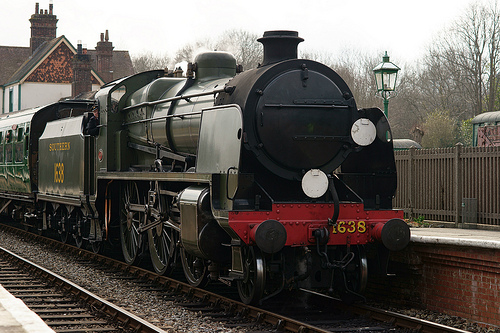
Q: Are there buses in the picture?
A: No, there are no buses.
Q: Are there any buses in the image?
A: No, there are no buses.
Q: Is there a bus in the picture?
A: No, there are no buses.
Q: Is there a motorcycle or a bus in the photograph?
A: No, there are no buses or motorcycles.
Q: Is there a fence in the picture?
A: Yes, there is a fence.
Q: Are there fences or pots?
A: Yes, there is a fence.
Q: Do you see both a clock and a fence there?
A: No, there is a fence but no clocks.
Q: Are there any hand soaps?
A: No, there are no hand soaps.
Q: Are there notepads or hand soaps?
A: No, there are no hand soaps or notepads.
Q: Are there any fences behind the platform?
A: Yes, there is a fence behind the platform.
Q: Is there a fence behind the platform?
A: Yes, there is a fence behind the platform.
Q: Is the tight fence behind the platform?
A: Yes, the fence is behind the platform.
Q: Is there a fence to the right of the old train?
A: Yes, there is a fence to the right of the train.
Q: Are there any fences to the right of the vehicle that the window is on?
A: Yes, there is a fence to the right of the train.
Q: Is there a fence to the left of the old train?
A: No, the fence is to the right of the train.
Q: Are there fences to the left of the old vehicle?
A: No, the fence is to the right of the train.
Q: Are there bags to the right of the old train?
A: No, there is a fence to the right of the train.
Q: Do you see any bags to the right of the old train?
A: No, there is a fence to the right of the train.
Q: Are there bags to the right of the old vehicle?
A: No, there is a fence to the right of the train.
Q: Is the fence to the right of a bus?
A: No, the fence is to the right of the train.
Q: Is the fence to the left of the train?
A: No, the fence is to the right of the train.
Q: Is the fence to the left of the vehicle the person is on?
A: No, the fence is to the right of the train.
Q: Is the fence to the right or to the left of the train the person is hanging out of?
A: The fence is to the right of the train.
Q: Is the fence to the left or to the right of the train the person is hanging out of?
A: The fence is to the right of the train.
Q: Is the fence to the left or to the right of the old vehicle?
A: The fence is to the right of the train.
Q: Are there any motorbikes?
A: No, there are no motorbikes.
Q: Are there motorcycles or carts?
A: No, there are no motorcycles or carts.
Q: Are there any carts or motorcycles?
A: No, there are no motorcycles or carts.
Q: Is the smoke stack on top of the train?
A: Yes, the smoke stack is on top of the train.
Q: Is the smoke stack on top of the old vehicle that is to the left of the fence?
A: Yes, the smoke stack is on top of the train.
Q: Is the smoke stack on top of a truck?
A: No, the smoke stack is on top of the train.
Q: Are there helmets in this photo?
A: No, there are no helmets.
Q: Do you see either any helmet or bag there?
A: No, there are no helmets or bags.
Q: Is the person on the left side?
A: Yes, the person is on the left of the image.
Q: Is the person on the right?
A: No, the person is on the left of the image.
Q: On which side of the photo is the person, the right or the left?
A: The person is on the left of the image.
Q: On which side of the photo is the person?
A: The person is on the left of the image.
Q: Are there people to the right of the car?
A: Yes, there is a person to the right of the car.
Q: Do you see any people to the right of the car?
A: Yes, there is a person to the right of the car.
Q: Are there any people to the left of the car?
A: No, the person is to the right of the car.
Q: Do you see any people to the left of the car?
A: No, the person is to the right of the car.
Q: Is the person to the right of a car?
A: Yes, the person is to the right of a car.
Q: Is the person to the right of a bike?
A: No, the person is to the right of a car.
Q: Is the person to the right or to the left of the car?
A: The person is to the right of the car.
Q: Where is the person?
A: The person is on the train.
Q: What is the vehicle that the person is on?
A: The vehicle is a train.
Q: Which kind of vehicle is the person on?
A: The person is on the train.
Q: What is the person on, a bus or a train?
A: The person is on a train.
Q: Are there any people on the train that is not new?
A: Yes, there is a person on the train.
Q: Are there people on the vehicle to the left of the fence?
A: Yes, there is a person on the train.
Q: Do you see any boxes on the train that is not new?
A: No, there is a person on the train.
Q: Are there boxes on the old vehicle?
A: No, there is a person on the train.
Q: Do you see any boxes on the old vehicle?
A: No, there is a person on the train.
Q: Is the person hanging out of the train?
A: Yes, the person is hanging out of the train.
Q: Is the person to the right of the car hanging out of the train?
A: Yes, the person is hanging out of the train.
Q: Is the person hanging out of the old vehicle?
A: Yes, the person is hanging out of the train.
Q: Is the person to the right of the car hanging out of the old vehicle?
A: Yes, the person is hanging out of the train.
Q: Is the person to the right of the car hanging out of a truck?
A: No, the person is hanging out of the train.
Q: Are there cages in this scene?
A: No, there are no cages.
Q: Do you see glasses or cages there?
A: No, there are no cages or glasses.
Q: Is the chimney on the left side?
A: Yes, the chimney is on the left of the image.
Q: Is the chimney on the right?
A: No, the chimney is on the left of the image.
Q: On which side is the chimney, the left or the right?
A: The chimney is on the left of the image.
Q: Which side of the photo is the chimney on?
A: The chimney is on the left of the image.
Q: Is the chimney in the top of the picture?
A: Yes, the chimney is in the top of the image.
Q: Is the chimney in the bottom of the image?
A: No, the chimney is in the top of the image.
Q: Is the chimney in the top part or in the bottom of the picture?
A: The chimney is in the top of the image.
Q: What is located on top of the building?
A: The chimney is on top of the building.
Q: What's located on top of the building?
A: The chimney is on top of the building.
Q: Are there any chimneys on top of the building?
A: Yes, there is a chimney on top of the building.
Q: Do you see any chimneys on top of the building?
A: Yes, there is a chimney on top of the building.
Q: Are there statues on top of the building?
A: No, there is a chimney on top of the building.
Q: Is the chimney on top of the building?
A: Yes, the chimney is on top of the building.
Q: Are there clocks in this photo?
A: No, there are no clocks.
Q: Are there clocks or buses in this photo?
A: No, there are no clocks or buses.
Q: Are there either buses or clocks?
A: No, there are no clocks or buses.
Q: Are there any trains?
A: Yes, there is a train.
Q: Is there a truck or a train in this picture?
A: Yes, there is a train.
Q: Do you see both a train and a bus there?
A: No, there is a train but no buses.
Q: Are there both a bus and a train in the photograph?
A: No, there is a train but no buses.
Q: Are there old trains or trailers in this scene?
A: Yes, there is an old train.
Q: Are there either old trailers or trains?
A: Yes, there is an old train.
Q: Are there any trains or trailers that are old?
A: Yes, the train is old.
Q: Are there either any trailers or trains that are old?
A: Yes, the train is old.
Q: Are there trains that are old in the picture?
A: Yes, there is an old train.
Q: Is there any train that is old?
A: Yes, there is a train that is old.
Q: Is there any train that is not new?
A: Yes, there is a old train.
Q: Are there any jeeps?
A: No, there are no jeeps.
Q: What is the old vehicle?
A: The vehicle is a train.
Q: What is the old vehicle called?
A: The vehicle is a train.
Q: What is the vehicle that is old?
A: The vehicle is a train.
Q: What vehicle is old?
A: The vehicle is a train.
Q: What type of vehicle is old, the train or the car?
A: The train is old.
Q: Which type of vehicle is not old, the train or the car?
A: The car is not old.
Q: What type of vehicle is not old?
A: The vehicle is a car.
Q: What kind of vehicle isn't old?
A: The vehicle is a car.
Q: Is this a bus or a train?
A: This is a train.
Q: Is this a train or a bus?
A: This is a train.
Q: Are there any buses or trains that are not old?
A: No, there is a train but it is old.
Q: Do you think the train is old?
A: Yes, the train is old.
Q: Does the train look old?
A: Yes, the train is old.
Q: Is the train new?
A: No, the train is old.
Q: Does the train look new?
A: No, the train is old.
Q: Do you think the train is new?
A: No, the train is old.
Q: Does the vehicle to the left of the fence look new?
A: No, the train is old.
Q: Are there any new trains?
A: No, there is a train but it is old.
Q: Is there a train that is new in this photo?
A: No, there is a train but it is old.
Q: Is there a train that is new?
A: No, there is a train but it is old.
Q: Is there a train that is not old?
A: No, there is a train but it is old.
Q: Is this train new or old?
A: The train is old.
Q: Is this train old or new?
A: The train is old.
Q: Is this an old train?
A: Yes, this is an old train.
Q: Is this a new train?
A: No, this is an old train.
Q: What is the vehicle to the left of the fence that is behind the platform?
A: The vehicle is a train.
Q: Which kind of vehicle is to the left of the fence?
A: The vehicle is a train.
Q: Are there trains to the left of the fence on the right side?
A: Yes, there is a train to the left of the fence.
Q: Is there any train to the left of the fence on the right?
A: Yes, there is a train to the left of the fence.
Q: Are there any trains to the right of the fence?
A: No, the train is to the left of the fence.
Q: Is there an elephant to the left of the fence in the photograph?
A: No, there is a train to the left of the fence.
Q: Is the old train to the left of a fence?
A: Yes, the train is to the left of a fence.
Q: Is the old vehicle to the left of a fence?
A: Yes, the train is to the left of a fence.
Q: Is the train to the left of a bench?
A: No, the train is to the left of a fence.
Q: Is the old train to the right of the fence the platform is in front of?
A: No, the train is to the left of the fence.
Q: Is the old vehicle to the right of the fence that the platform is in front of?
A: No, the train is to the left of the fence.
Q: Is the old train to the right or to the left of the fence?
A: The train is to the left of the fence.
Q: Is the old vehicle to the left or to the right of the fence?
A: The train is to the left of the fence.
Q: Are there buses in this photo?
A: No, there are no buses.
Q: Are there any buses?
A: No, there are no buses.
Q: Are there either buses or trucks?
A: No, there are no buses or trucks.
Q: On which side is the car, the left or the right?
A: The car is on the left of the image.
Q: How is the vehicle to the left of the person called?
A: The vehicle is a car.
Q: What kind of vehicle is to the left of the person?
A: The vehicle is a car.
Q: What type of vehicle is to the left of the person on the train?
A: The vehicle is a car.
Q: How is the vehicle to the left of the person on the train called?
A: The vehicle is a car.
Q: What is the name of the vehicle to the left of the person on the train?
A: The vehicle is a car.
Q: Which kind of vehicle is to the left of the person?
A: The vehicle is a car.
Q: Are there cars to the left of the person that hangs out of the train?
A: Yes, there is a car to the left of the person.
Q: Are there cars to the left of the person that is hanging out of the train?
A: Yes, there is a car to the left of the person.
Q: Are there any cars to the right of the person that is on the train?
A: No, the car is to the left of the person.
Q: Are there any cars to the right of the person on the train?
A: No, the car is to the left of the person.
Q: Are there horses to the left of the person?
A: No, there is a car to the left of the person.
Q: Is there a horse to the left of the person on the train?
A: No, there is a car to the left of the person.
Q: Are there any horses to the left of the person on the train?
A: No, there is a car to the left of the person.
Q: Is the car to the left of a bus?
A: No, the car is to the left of a person.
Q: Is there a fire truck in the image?
A: No, there are no fire trucks.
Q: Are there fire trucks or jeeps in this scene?
A: No, there are no fire trucks or jeeps.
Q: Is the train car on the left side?
A: Yes, the train car is on the left of the image.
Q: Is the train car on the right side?
A: No, the train car is on the left of the image.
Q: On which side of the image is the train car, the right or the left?
A: The train car is on the left of the image.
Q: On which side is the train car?
A: The train car is on the left of the image.